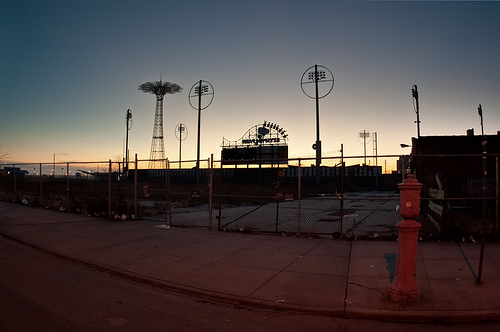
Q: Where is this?
A: This is at the street.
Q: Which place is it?
A: It is a street.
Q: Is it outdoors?
A: Yes, it is outdoors.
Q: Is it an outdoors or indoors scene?
A: It is outdoors.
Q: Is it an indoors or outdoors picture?
A: It is outdoors.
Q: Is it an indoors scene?
A: No, it is outdoors.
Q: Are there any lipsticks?
A: No, there are no lipsticks.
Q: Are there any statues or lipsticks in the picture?
A: No, there are no lipsticks or statues.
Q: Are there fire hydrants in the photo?
A: Yes, there is a fire hydrant.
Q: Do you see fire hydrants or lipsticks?
A: Yes, there is a fire hydrant.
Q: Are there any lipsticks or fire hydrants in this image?
A: Yes, there is a fire hydrant.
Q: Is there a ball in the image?
A: No, there are no balls.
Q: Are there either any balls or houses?
A: No, there are no balls or houses.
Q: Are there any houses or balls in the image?
A: No, there are no balls or houses.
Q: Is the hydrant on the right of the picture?
A: Yes, the hydrant is on the right of the image.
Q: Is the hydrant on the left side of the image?
A: No, the hydrant is on the right of the image.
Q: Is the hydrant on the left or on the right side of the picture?
A: The hydrant is on the right of the image.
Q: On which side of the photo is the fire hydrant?
A: The fire hydrant is on the right of the image.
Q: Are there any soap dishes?
A: No, there are no soap dishes.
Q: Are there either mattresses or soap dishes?
A: No, there are no soap dishes or mattresses.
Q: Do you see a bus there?
A: No, there are no buses.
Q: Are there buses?
A: No, there are no buses.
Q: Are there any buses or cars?
A: No, there are no buses or cars.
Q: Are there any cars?
A: No, there are no cars.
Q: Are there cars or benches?
A: No, there are no cars or benches.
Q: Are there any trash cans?
A: No, there are no trash cans.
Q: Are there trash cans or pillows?
A: No, there are no trash cans or pillows.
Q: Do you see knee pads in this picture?
A: No, there are no knee pads.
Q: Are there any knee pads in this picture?
A: No, there are no knee pads.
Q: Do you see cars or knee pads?
A: No, there are no knee pads or cars.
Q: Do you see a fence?
A: Yes, there is a fence.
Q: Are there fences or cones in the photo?
A: Yes, there is a fence.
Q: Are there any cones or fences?
A: Yes, there is a fence.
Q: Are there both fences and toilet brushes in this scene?
A: No, there is a fence but no toilet brushes.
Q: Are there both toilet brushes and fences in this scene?
A: No, there is a fence but no toilet brushes.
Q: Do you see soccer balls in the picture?
A: No, there are no soccer balls.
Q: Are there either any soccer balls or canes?
A: No, there are no soccer balls or canes.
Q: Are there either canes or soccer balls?
A: No, there are no soccer balls or canes.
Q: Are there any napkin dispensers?
A: No, there are no napkin dispensers.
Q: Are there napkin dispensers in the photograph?
A: No, there are no napkin dispensers.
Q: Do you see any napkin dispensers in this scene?
A: No, there are no napkin dispensers.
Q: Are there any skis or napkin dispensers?
A: No, there are no napkin dispensers or skis.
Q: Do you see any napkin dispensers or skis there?
A: No, there are no napkin dispensers or skis.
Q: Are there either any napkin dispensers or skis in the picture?
A: No, there are no napkin dispensers or skis.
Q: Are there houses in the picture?
A: No, there are no houses.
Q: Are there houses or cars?
A: No, there are no houses or cars.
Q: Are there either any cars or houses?
A: No, there are no houses or cars.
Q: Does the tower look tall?
A: Yes, the tower is tall.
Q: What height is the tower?
A: The tower is tall.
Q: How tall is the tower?
A: The tower is tall.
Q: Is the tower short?
A: No, the tower is tall.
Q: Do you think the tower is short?
A: No, the tower is tall.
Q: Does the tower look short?
A: No, the tower is tall.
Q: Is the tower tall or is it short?
A: The tower is tall.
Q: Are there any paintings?
A: No, there are no paintings.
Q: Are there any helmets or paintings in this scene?
A: No, there are no paintings or helmets.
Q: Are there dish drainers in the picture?
A: No, there are no dish drainers.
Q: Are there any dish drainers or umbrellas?
A: No, there are no dish drainers or umbrellas.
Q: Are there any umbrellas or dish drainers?
A: No, there are no dish drainers or umbrellas.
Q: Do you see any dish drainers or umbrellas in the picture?
A: No, there are no dish drainers or umbrellas.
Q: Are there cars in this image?
A: No, there are no cars.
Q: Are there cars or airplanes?
A: No, there are no cars or airplanes.